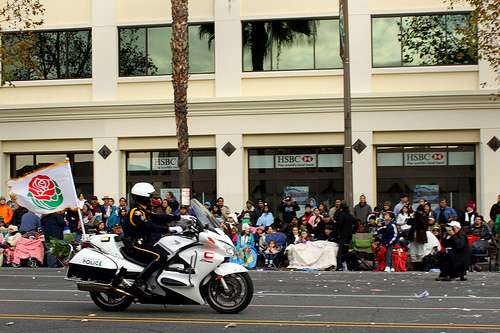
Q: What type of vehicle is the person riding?
A: Motorcycle.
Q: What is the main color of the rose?
A: Red.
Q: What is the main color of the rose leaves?
A: Green.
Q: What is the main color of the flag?
A: White.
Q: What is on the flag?
A: A rose.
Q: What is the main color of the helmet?
A: White.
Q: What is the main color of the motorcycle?
A: White.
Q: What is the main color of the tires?
A: Black.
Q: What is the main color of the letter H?
A: Black.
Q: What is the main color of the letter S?
A: Black.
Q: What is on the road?
A: A motorcycle.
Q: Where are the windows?
A: On the building.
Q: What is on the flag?
A: A rose.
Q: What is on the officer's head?
A: A helmet.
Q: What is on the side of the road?
A: Large group of people.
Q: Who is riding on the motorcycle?
A: Police officer.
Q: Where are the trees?
A: In front of the building.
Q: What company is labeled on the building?
A: HSBC.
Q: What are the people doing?
A: Watching a parade.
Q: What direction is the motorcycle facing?
A: To the right.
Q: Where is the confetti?
A: On the street.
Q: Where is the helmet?
A: On the head.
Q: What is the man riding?
A: Motorcycle.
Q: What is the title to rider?
A: Policeman.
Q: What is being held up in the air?
A: A banner.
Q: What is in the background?
A: A building.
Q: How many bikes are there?
A: 1.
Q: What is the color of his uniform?
A: Black.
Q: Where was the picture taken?
A: At a parade.